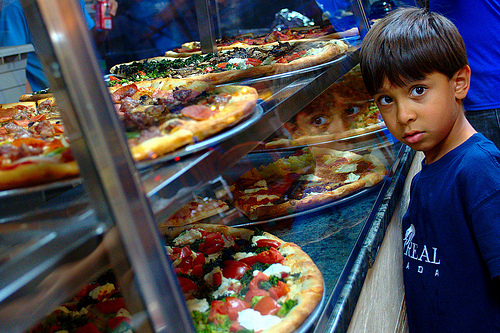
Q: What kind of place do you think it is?
A: It is a display.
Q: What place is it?
A: It is a display.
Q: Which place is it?
A: It is a display.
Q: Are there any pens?
A: No, there are no pens.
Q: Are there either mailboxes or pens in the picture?
A: No, there are no pens or mailboxes.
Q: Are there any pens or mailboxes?
A: No, there are no pens or mailboxes.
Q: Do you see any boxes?
A: No, there are no boxes.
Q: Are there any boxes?
A: No, there are no boxes.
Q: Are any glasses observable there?
A: No, there are no glasses.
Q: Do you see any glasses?
A: No, there are no glasses.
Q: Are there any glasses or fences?
A: No, there are no glasses or fences.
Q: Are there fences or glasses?
A: No, there are no glasses or fences.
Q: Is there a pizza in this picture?
A: Yes, there is a pizza.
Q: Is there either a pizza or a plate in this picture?
A: Yes, there is a pizza.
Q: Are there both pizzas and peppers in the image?
A: No, there is a pizza but no peppers.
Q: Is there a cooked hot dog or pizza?
A: Yes, there is a cooked pizza.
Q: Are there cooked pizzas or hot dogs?
A: Yes, there is a cooked pizza.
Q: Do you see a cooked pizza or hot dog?
A: Yes, there is a cooked pizza.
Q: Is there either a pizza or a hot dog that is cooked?
A: Yes, the pizza is cooked.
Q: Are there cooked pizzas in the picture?
A: Yes, there is a cooked pizza.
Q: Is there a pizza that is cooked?
A: Yes, there is a pizza that is cooked.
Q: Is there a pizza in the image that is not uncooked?
A: Yes, there is an cooked pizza.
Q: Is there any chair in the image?
A: No, there are no chairs.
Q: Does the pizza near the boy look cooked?
A: Yes, the pizza is cooked.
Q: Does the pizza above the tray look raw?
A: No, the pizza is cooked.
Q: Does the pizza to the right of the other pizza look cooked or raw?
A: The pizza is cooked.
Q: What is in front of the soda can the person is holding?
A: The pizza is in front of the soda can.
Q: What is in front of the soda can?
A: The pizza is in front of the soda can.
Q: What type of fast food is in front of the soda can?
A: The food is a pizza.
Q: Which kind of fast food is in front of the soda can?
A: The food is a pizza.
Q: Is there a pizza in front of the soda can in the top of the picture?
A: Yes, there is a pizza in front of the soda can.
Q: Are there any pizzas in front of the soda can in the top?
A: Yes, there is a pizza in front of the soda can.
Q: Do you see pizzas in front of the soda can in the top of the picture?
A: Yes, there is a pizza in front of the soda can.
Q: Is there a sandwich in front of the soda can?
A: No, there is a pizza in front of the soda can.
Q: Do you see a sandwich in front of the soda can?
A: No, there is a pizza in front of the soda can.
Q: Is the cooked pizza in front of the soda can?
A: Yes, the pizza is in front of the soda can.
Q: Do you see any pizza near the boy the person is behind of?
A: Yes, there is a pizza near the boy.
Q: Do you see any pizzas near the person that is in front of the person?
A: Yes, there is a pizza near the boy.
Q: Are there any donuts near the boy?
A: No, there is a pizza near the boy.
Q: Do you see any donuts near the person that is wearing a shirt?
A: No, there is a pizza near the boy.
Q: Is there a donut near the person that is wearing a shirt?
A: No, there is a pizza near the boy.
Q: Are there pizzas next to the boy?
A: Yes, there is a pizza next to the boy.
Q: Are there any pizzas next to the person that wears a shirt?
A: Yes, there is a pizza next to the boy.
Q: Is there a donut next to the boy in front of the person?
A: No, there is a pizza next to the boy.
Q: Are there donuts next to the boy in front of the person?
A: No, there is a pizza next to the boy.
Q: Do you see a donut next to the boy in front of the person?
A: No, there is a pizza next to the boy.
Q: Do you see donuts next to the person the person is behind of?
A: No, there is a pizza next to the boy.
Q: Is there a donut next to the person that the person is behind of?
A: No, there is a pizza next to the boy.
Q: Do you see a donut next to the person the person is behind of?
A: No, there is a pizza next to the boy.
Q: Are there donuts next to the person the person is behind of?
A: No, there is a pizza next to the boy.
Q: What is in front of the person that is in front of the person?
A: The pizza is in front of the boy.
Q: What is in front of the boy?
A: The pizza is in front of the boy.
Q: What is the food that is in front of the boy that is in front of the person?
A: The food is a pizza.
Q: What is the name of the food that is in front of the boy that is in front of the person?
A: The food is a pizza.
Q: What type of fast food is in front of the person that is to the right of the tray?
A: The food is a pizza.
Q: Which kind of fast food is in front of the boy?
A: The food is a pizza.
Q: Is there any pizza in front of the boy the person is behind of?
A: Yes, there is a pizza in front of the boy.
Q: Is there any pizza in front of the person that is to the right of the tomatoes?
A: Yes, there is a pizza in front of the boy.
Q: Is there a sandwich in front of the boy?
A: No, there is a pizza in front of the boy.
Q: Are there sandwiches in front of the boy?
A: No, there is a pizza in front of the boy.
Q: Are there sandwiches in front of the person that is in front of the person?
A: No, there is a pizza in front of the boy.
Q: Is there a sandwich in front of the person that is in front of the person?
A: No, there is a pizza in front of the boy.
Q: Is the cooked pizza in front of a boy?
A: Yes, the pizza is in front of a boy.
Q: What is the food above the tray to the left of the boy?
A: The food is a pizza.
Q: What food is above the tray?
A: The food is a pizza.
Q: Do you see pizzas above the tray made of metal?
A: Yes, there is a pizza above the tray.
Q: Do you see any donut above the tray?
A: No, there is a pizza above the tray.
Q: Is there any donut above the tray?
A: No, there is a pizza above the tray.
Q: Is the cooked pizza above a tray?
A: Yes, the pizza is above a tray.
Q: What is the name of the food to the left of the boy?
A: The food is a pizza.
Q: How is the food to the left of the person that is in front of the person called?
A: The food is a pizza.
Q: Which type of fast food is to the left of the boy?
A: The food is a pizza.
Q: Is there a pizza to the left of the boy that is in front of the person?
A: Yes, there is a pizza to the left of the boy.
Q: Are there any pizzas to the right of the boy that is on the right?
A: No, the pizza is to the left of the boy.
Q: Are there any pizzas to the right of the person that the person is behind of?
A: No, the pizza is to the left of the boy.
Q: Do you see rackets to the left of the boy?
A: No, there is a pizza to the left of the boy.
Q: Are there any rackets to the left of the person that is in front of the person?
A: No, there is a pizza to the left of the boy.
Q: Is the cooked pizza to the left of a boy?
A: Yes, the pizza is to the left of a boy.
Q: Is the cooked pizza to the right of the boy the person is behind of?
A: No, the pizza is to the left of the boy.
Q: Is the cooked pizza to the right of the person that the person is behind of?
A: No, the pizza is to the left of the boy.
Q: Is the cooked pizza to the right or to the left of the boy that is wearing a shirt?
A: The pizza is to the left of the boy.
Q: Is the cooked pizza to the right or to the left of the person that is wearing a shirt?
A: The pizza is to the left of the boy.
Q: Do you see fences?
A: No, there are no fences.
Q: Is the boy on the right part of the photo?
A: Yes, the boy is on the right of the image.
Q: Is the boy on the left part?
A: No, the boy is on the right of the image.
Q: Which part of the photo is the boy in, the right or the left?
A: The boy is on the right of the image.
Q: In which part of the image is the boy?
A: The boy is on the right of the image.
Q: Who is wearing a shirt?
A: The boy is wearing a shirt.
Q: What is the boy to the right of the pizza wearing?
A: The boy is wearing a shirt.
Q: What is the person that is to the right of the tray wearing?
A: The boy is wearing a shirt.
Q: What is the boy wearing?
A: The boy is wearing a shirt.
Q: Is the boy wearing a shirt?
A: Yes, the boy is wearing a shirt.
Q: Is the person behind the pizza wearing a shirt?
A: Yes, the boy is wearing a shirt.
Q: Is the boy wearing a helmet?
A: No, the boy is wearing a shirt.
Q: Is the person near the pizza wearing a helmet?
A: No, the boy is wearing a shirt.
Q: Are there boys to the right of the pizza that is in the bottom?
A: Yes, there is a boy to the right of the pizza.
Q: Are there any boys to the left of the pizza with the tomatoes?
A: No, the boy is to the right of the pizza.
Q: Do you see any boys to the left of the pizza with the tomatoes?
A: No, the boy is to the right of the pizza.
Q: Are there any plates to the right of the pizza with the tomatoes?
A: No, there is a boy to the right of the pizza.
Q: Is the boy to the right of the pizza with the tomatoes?
A: Yes, the boy is to the right of the pizza.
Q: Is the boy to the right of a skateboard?
A: No, the boy is to the right of the pizza.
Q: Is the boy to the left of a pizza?
A: No, the boy is to the right of a pizza.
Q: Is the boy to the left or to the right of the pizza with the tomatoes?
A: The boy is to the right of the pizza.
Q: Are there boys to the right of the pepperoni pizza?
A: Yes, there is a boy to the right of the pizza.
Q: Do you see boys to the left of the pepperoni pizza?
A: No, the boy is to the right of the pizza.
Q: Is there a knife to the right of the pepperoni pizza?
A: No, there is a boy to the right of the pizza.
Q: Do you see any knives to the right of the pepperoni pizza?
A: No, there is a boy to the right of the pizza.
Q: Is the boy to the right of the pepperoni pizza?
A: Yes, the boy is to the right of the pizza.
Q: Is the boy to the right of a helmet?
A: No, the boy is to the right of the pizza.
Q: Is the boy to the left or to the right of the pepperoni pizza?
A: The boy is to the right of the pizza.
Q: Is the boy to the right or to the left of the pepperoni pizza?
A: The boy is to the right of the pizza.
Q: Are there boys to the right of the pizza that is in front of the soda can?
A: Yes, there is a boy to the right of the pizza.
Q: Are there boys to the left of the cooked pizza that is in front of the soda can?
A: No, the boy is to the right of the pizza.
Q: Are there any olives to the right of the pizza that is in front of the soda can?
A: No, there is a boy to the right of the pizza.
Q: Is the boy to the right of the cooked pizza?
A: Yes, the boy is to the right of the pizza.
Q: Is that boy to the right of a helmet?
A: No, the boy is to the right of the pizza.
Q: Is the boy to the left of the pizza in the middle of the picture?
A: No, the boy is to the right of the pizza.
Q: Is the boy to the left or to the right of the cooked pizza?
A: The boy is to the right of the pizza.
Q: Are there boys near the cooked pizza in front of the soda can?
A: Yes, there is a boy near the pizza.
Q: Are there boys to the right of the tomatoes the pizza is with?
A: Yes, there is a boy to the right of the tomatoes.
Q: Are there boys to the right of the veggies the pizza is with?
A: Yes, there is a boy to the right of the tomatoes.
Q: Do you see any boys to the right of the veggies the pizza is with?
A: Yes, there is a boy to the right of the tomatoes.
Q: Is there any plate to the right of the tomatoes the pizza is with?
A: No, there is a boy to the right of the tomatoes.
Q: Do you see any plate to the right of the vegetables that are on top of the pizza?
A: No, there is a boy to the right of the tomatoes.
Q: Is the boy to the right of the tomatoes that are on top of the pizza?
A: Yes, the boy is to the right of the tomatoes.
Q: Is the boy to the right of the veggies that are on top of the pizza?
A: Yes, the boy is to the right of the tomatoes.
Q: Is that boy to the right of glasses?
A: No, the boy is to the right of the tomatoes.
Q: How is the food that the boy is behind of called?
A: The food is a pizza.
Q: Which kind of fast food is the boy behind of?
A: The boy is behind the pizza.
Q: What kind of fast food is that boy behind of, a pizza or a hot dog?
A: The boy is behind a pizza.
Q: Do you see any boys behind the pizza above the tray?
A: Yes, there is a boy behind the pizza.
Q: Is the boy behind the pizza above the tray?
A: Yes, the boy is behind the pizza.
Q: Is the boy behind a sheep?
A: No, the boy is behind the pizza.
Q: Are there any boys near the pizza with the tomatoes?
A: Yes, there is a boy near the pizza.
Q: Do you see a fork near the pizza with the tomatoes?
A: No, there is a boy near the pizza.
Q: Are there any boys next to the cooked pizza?
A: Yes, there is a boy next to the pizza.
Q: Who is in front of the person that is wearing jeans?
A: The boy is in front of the person.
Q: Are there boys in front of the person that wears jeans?
A: Yes, there is a boy in front of the person.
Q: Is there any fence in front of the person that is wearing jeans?
A: No, there is a boy in front of the person.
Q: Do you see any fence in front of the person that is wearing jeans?
A: No, there is a boy in front of the person.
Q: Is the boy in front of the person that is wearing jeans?
A: Yes, the boy is in front of the person.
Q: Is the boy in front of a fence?
A: No, the boy is in front of the person.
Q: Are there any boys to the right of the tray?
A: Yes, there is a boy to the right of the tray.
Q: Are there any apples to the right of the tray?
A: No, there is a boy to the right of the tray.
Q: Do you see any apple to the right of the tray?
A: No, there is a boy to the right of the tray.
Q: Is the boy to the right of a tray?
A: Yes, the boy is to the right of a tray.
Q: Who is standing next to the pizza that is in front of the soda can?
A: The boy is standing next to the pizza.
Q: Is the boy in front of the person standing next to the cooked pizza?
A: Yes, the boy is standing next to the pizza.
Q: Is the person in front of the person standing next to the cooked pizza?
A: Yes, the boy is standing next to the pizza.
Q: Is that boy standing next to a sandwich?
A: No, the boy is standing next to the pizza.